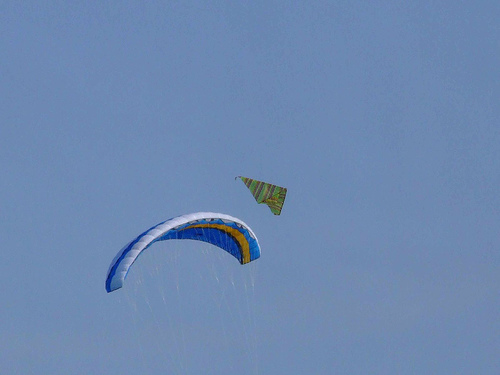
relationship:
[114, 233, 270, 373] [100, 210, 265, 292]
strings on parasail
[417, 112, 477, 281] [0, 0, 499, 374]
clouds in blue sky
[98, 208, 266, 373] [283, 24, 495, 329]
parasail in sky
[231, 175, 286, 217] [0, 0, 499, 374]
flying objects flying in blue sky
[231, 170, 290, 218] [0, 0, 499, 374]
flying objects in blue sky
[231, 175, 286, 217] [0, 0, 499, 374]
flying objects in blue sky